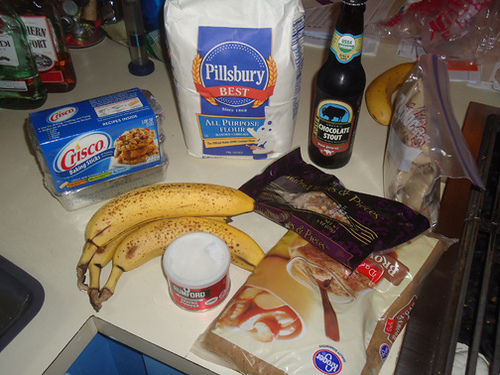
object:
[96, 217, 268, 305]
bananas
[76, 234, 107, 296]
stem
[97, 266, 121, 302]
stem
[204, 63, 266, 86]
text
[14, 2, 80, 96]
liquid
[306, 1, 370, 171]
bottle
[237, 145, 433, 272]
bag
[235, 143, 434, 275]
food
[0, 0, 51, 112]
bottles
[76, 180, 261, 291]
banana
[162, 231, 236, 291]
lid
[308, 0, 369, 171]
beer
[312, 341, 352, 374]
logo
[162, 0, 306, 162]
flour bag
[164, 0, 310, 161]
flour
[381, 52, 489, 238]
bag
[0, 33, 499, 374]
table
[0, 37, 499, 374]
counter